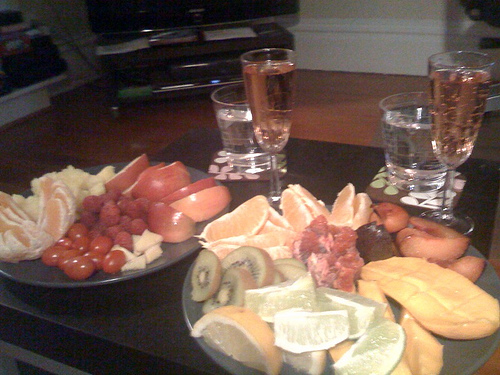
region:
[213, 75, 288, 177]
The glass is clear.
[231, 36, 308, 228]
The glass is clear.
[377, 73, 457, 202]
The glass is clear.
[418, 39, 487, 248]
The glass is clear.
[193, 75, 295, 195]
The glass is on a coaster.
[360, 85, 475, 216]
The glass is on a coaster.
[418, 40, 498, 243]
The glass is full.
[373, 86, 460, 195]
The glass is full.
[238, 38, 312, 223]
The glass is full.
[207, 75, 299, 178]
The glass is full.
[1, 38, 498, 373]
a meal of fruit and wine ready to be consumed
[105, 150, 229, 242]
apple slices are on one of these fruit plates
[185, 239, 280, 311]
sliced kiwi fruit is on one of these fruit plates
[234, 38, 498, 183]
the sparkling drinks in the tall glasses could be champagne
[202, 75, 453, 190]
water glasses beside the wine glasses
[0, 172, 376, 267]
segmented oranges are on both of these fruit plates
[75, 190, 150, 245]
raspberries are on one of these fruit plates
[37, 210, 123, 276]
grapes are on one of these fruit plates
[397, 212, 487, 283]
peach slices are on one of these fruit plates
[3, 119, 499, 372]
fruit plates and wine are on a black coffee table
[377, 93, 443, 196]
glass of water sitting on a napkin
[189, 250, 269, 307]
sliced kiwi fruits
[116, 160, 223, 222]
sliced apples on a plate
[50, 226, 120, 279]
tomatoes on a plate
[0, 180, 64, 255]
sections of an orange on a plate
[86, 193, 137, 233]
raspberries in the center of a plate of fruit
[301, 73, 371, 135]
wooden floor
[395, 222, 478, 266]
sliced peaches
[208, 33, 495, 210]
four drink glasses on a table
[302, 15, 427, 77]
white baseboard of a wall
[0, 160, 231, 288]
fruit and vegetables on agrey plate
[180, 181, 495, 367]
fruit and vegetables on a grey plate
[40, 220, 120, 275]
cherry tomatoes on a grey plate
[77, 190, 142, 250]
red strawberries on a grey plate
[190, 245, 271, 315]
sliced kiwi on a grey plate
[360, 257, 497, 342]
a slice of bread on a grey plate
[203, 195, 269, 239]
slice of orange on a grey plate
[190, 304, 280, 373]
slice of orange on a grey plate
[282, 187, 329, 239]
slice of orange on a grey plate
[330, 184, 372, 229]
slice of orange on a grey plate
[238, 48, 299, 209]
a glass of champagne on the table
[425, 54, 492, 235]
a glass of champagne on the table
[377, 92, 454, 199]
a glass of water on the table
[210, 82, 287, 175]
a glass of water on the table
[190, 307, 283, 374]
a slice of orange on a plate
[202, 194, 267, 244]
a slice of orange on a plate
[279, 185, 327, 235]
a slice of orange on a plate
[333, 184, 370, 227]
a slice of orange on a plate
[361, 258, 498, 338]
bread on a plate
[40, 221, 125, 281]
cherry tomatoes on a plate